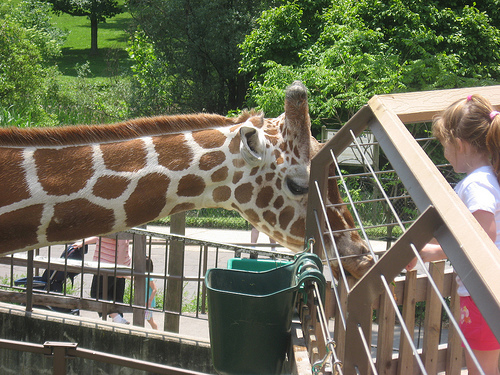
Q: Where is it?
A: This is at the zoo.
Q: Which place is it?
A: It is a zoo.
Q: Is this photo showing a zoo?
A: Yes, it is showing a zoo.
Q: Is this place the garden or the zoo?
A: It is the zoo.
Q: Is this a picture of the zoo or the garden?
A: It is showing the zoo.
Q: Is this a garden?
A: No, it is a zoo.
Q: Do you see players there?
A: No, there are no players.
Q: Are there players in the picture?
A: No, there are no players.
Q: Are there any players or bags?
A: No, there are no players or bags.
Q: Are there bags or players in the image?
A: No, there are no players or bags.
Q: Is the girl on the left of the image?
A: Yes, the girl is on the left of the image.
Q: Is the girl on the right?
A: No, the girl is on the left of the image.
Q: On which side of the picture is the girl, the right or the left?
A: The girl is on the left of the image.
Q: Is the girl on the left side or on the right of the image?
A: The girl is on the left of the image.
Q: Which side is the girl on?
A: The girl is on the left of the image.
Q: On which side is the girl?
A: The girl is on the left of the image.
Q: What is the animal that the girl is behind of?
A: The animal is a giraffe.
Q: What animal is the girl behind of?
A: The girl is behind the giraffe.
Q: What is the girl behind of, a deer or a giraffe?
A: The girl is behind a giraffe.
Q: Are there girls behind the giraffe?
A: Yes, there is a girl behind the giraffe.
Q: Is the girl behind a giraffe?
A: Yes, the girl is behind a giraffe.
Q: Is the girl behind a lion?
A: No, the girl is behind a giraffe.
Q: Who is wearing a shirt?
A: The girl is wearing a shirt.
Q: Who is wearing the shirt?
A: The girl is wearing a shirt.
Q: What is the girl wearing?
A: The girl is wearing a shirt.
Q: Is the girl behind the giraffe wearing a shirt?
A: Yes, the girl is wearing a shirt.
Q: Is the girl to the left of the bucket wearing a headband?
A: No, the girl is wearing a shirt.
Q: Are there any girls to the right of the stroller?
A: Yes, there is a girl to the right of the stroller.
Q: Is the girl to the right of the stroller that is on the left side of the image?
A: Yes, the girl is to the right of the stroller.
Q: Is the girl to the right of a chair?
A: No, the girl is to the right of the stroller.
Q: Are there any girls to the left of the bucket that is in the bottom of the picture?
A: Yes, there is a girl to the left of the bucket.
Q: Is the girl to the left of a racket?
A: No, the girl is to the left of the bucket.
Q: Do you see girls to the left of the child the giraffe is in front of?
A: Yes, there is a girl to the left of the kid.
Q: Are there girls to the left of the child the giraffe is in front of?
A: Yes, there is a girl to the left of the kid.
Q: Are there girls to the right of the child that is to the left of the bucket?
A: No, the girl is to the left of the child.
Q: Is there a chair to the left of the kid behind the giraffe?
A: No, there is a girl to the left of the child.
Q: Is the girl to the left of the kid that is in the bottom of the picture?
A: Yes, the girl is to the left of the kid.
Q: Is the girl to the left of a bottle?
A: No, the girl is to the left of the kid.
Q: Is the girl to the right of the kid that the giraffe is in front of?
A: No, the girl is to the left of the kid.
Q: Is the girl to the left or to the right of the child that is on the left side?
A: The girl is to the left of the child.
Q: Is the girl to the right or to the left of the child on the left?
A: The girl is to the left of the child.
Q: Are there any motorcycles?
A: No, there are no motorcycles.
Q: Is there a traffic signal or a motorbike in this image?
A: No, there are no motorcycles or traffic lights.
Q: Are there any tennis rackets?
A: No, there are no tennis rackets.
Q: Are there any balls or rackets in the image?
A: No, there are no rackets or balls.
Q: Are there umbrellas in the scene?
A: No, there are no umbrellas.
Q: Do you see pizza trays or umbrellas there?
A: No, there are no umbrellas or pizza trays.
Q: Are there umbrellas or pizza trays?
A: No, there are no umbrellas or pizza trays.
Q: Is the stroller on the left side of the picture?
A: Yes, the stroller is on the left of the image.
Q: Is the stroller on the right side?
A: No, the stroller is on the left of the image.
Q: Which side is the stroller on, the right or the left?
A: The stroller is on the left of the image.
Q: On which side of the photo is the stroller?
A: The stroller is on the left of the image.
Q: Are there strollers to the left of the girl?
A: Yes, there is a stroller to the left of the girl.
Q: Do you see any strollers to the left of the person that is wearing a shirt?
A: Yes, there is a stroller to the left of the girl.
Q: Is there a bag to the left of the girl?
A: No, there is a stroller to the left of the girl.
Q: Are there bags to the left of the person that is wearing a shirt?
A: No, there is a stroller to the left of the girl.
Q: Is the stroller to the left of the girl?
A: Yes, the stroller is to the left of the girl.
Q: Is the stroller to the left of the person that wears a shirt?
A: Yes, the stroller is to the left of the girl.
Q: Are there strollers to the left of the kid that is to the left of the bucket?
A: Yes, there is a stroller to the left of the child.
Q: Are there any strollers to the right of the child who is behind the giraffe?
A: No, the stroller is to the left of the child.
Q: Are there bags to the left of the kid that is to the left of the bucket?
A: No, there is a stroller to the left of the kid.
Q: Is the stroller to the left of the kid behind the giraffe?
A: Yes, the stroller is to the left of the kid.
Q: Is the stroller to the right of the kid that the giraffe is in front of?
A: No, the stroller is to the left of the child.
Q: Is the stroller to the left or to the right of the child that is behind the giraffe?
A: The stroller is to the left of the child.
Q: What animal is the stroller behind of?
A: The stroller is behind the giraffe.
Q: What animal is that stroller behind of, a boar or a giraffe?
A: The stroller is behind a giraffe.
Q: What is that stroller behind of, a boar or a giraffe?
A: The stroller is behind a giraffe.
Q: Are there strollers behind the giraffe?
A: Yes, there is a stroller behind the giraffe.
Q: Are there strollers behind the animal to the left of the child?
A: Yes, there is a stroller behind the giraffe.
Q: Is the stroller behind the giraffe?
A: Yes, the stroller is behind the giraffe.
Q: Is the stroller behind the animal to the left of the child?
A: Yes, the stroller is behind the giraffe.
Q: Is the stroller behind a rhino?
A: No, the stroller is behind the giraffe.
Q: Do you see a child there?
A: Yes, there is a child.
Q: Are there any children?
A: Yes, there is a child.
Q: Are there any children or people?
A: Yes, there is a child.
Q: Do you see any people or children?
A: Yes, there is a child.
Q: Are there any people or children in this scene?
A: Yes, there is a child.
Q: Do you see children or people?
A: Yes, there is a child.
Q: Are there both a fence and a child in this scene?
A: Yes, there are both a child and a fence.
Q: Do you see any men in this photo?
A: No, there are no men.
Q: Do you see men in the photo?
A: No, there are no men.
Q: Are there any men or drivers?
A: No, there are no men or drivers.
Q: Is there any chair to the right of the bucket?
A: No, there is a child to the right of the bucket.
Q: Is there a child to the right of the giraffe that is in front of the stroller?
A: Yes, there is a child to the right of the giraffe.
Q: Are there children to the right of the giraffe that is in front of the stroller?
A: Yes, there is a child to the right of the giraffe.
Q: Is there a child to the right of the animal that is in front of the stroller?
A: Yes, there is a child to the right of the giraffe.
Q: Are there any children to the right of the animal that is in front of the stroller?
A: Yes, there is a child to the right of the giraffe.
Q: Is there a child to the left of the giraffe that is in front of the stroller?
A: No, the child is to the right of the giraffe.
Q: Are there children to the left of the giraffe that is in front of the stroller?
A: No, the child is to the right of the giraffe.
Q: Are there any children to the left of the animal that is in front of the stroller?
A: No, the child is to the right of the giraffe.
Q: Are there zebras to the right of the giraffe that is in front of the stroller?
A: No, there is a child to the right of the giraffe.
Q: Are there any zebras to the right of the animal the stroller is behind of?
A: No, there is a child to the right of the giraffe.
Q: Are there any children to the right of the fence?
A: Yes, there is a child to the right of the fence.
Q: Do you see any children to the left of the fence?
A: No, the child is to the right of the fence.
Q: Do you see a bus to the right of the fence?
A: No, there is a child to the right of the fence.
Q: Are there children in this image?
A: Yes, there is a child.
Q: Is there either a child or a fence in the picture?
A: Yes, there is a child.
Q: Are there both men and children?
A: No, there is a child but no men.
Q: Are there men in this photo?
A: No, there are no men.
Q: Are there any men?
A: No, there are no men.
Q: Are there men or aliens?
A: No, there are no men or aliens.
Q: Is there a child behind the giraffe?
A: Yes, there is a child behind the giraffe.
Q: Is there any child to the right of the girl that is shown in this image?
A: Yes, there is a child to the right of the girl.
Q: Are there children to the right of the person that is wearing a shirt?
A: Yes, there is a child to the right of the girl.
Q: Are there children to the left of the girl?
A: No, the child is to the right of the girl.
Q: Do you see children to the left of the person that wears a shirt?
A: No, the child is to the right of the girl.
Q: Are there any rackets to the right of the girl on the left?
A: No, there is a child to the right of the girl.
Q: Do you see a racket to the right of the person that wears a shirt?
A: No, there is a child to the right of the girl.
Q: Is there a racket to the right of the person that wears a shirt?
A: No, there is a child to the right of the girl.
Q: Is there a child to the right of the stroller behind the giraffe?
A: Yes, there is a child to the right of the stroller.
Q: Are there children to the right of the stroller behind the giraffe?
A: Yes, there is a child to the right of the stroller.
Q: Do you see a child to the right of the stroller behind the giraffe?
A: Yes, there is a child to the right of the stroller.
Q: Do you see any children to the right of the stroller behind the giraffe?
A: Yes, there is a child to the right of the stroller.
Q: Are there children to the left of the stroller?
A: No, the child is to the right of the stroller.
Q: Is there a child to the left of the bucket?
A: Yes, there is a child to the left of the bucket.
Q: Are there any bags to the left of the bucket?
A: No, there is a child to the left of the bucket.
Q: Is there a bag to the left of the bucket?
A: No, there is a child to the left of the bucket.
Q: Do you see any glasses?
A: No, there are no glasses.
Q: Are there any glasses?
A: No, there are no glasses.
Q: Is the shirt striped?
A: Yes, the shirt is striped.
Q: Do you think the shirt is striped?
A: Yes, the shirt is striped.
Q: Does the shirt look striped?
A: Yes, the shirt is striped.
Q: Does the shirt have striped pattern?
A: Yes, the shirt is striped.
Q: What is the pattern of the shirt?
A: The shirt is striped.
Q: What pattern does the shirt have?
A: The shirt has striped pattern.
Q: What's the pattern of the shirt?
A: The shirt is striped.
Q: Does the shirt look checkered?
A: No, the shirt is striped.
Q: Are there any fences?
A: Yes, there is a fence.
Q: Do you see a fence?
A: Yes, there is a fence.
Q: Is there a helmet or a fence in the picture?
A: Yes, there is a fence.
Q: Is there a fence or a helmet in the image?
A: Yes, there is a fence.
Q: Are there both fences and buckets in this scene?
A: Yes, there are both a fence and a bucket.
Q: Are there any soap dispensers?
A: No, there are no soap dispensers.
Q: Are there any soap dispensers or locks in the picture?
A: No, there are no soap dispensers or locks.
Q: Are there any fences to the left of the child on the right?
A: Yes, there is a fence to the left of the kid.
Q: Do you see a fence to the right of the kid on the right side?
A: No, the fence is to the left of the kid.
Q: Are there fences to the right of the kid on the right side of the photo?
A: No, the fence is to the left of the kid.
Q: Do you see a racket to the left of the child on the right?
A: No, there is a fence to the left of the child.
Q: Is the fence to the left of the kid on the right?
A: Yes, the fence is to the left of the child.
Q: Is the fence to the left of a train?
A: No, the fence is to the left of the child.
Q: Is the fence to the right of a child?
A: No, the fence is to the left of a child.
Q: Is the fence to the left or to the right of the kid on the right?
A: The fence is to the left of the kid.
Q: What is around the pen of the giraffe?
A: The fence is around the pen.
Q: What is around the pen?
A: The fence is around the pen.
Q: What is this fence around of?
A: The fence is around the pen.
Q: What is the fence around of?
A: The fence is around the pen.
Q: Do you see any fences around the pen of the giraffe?
A: Yes, there is a fence around the pen.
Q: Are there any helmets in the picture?
A: No, there are no helmets.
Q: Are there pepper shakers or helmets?
A: No, there are no helmets or pepper shakers.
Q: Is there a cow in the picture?
A: No, there are no cows.